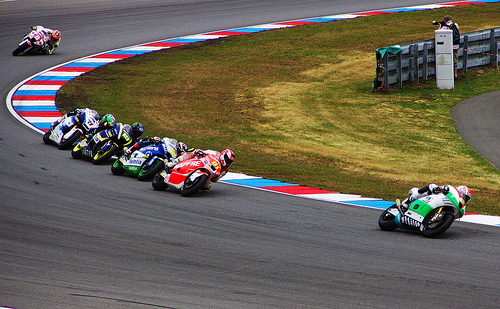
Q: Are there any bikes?
A: Yes, there is a bike.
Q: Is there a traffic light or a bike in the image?
A: Yes, there is a bike.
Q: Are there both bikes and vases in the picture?
A: No, there is a bike but no vases.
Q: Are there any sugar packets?
A: No, there are no sugar packets.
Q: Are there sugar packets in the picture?
A: No, there are no sugar packets.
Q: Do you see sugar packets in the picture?
A: No, there are no sugar packets.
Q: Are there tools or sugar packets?
A: No, there are no sugar packets or tools.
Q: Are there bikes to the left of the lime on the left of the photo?
A: Yes, there is a bike to the left of the lime.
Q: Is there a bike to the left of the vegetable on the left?
A: Yes, there is a bike to the left of the lime.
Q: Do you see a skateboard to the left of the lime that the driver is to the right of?
A: No, there is a bike to the left of the lime.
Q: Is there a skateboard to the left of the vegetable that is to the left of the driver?
A: No, there is a bike to the left of the lime.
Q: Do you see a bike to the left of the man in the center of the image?
A: Yes, there is a bike to the left of the man.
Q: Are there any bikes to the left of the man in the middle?
A: Yes, there is a bike to the left of the man.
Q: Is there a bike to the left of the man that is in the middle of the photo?
A: Yes, there is a bike to the left of the man.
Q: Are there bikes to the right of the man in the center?
A: No, the bike is to the left of the man.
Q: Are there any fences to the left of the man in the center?
A: No, there is a bike to the left of the man.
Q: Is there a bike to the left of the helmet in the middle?
A: Yes, there is a bike to the left of the helmet.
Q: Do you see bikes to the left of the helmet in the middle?
A: Yes, there is a bike to the left of the helmet.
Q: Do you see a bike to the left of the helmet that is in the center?
A: Yes, there is a bike to the left of the helmet.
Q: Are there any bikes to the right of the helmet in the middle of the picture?
A: No, the bike is to the left of the helmet.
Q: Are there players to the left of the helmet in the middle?
A: No, there is a bike to the left of the helmet.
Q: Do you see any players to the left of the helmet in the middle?
A: No, there is a bike to the left of the helmet.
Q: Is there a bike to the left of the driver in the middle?
A: Yes, there is a bike to the left of the driver.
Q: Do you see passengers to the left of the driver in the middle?
A: No, there is a bike to the left of the driver.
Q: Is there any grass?
A: Yes, there is grass.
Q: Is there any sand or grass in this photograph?
A: Yes, there is grass.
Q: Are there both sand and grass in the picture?
A: No, there is grass but no sand.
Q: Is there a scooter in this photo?
A: No, there are no scooters.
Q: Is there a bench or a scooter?
A: No, there are no scooters or benches.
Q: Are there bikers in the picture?
A: Yes, there is a biker.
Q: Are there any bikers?
A: Yes, there is a biker.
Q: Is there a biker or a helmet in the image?
A: Yes, there is a biker.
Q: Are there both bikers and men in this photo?
A: Yes, there are both a biker and men.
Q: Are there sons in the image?
A: No, there are no sons.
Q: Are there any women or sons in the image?
A: No, there are no sons or women.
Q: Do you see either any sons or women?
A: No, there are no sons or women.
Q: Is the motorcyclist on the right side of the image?
A: Yes, the motorcyclist is on the right of the image.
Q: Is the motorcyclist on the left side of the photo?
A: No, the motorcyclist is on the right of the image.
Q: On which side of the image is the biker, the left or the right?
A: The biker is on the right of the image.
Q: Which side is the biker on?
A: The biker is on the right of the image.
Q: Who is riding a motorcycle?
A: The biker is riding a motorcycle.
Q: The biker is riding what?
A: The biker is riding a motorcycle.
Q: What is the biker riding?
A: The biker is riding a motorcycle.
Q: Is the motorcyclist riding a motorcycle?
A: Yes, the motorcyclist is riding a motorcycle.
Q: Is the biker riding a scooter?
A: No, the biker is riding a motorcycle.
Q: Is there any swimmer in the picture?
A: No, there are no swimmers.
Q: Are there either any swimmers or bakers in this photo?
A: No, there are no swimmers or bakers.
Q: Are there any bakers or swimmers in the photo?
A: No, there are no swimmers or bakers.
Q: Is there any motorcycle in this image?
A: Yes, there is a motorcycle.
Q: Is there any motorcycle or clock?
A: Yes, there is a motorcycle.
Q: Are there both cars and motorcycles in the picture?
A: No, there is a motorcycle but no cars.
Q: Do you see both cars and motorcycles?
A: No, there is a motorcycle but no cars.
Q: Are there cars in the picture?
A: No, there are no cars.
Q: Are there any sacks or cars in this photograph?
A: No, there are no cars or sacks.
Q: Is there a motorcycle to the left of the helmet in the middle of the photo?
A: Yes, there is a motorcycle to the left of the helmet.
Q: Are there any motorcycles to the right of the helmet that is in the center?
A: No, the motorcycle is to the left of the helmet.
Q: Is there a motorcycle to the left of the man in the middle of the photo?
A: Yes, there is a motorcycle to the left of the man.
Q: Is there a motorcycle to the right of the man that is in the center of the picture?
A: No, the motorcycle is to the left of the man.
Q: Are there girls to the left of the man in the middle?
A: No, there is a motorcycle to the left of the man.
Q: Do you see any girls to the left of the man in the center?
A: No, there is a motorcycle to the left of the man.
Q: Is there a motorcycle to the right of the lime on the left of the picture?
A: Yes, there is a motorcycle to the right of the lime.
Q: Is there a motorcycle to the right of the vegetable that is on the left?
A: Yes, there is a motorcycle to the right of the lime.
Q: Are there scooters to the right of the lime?
A: No, there is a motorcycle to the right of the lime.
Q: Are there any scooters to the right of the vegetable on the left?
A: No, there is a motorcycle to the right of the lime.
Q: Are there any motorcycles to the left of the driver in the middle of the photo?
A: Yes, there is a motorcycle to the left of the driver.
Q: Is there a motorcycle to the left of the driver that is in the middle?
A: Yes, there is a motorcycle to the left of the driver.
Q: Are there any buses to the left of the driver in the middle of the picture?
A: No, there is a motorcycle to the left of the driver.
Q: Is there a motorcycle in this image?
A: Yes, there is a motorcycle.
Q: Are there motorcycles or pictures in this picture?
A: Yes, there is a motorcycle.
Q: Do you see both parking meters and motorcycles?
A: No, there is a motorcycle but no parking meters.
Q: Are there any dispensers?
A: No, there are no dispensers.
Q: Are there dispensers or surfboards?
A: No, there are no dispensers or surfboards.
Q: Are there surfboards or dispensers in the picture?
A: No, there are no dispensers or surfboards.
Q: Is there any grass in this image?
A: Yes, there is grass.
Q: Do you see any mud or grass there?
A: Yes, there is grass.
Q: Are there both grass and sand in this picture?
A: No, there is grass but no sand.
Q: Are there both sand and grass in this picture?
A: No, there is grass but no sand.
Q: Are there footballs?
A: No, there are no footballs.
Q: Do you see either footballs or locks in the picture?
A: No, there are no footballs or locks.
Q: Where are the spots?
A: The spots are on the road.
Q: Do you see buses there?
A: No, there are no buses.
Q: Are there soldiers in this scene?
A: No, there are no soldiers.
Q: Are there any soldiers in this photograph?
A: No, there are no soldiers.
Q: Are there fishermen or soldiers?
A: No, there are no soldiers or fishermen.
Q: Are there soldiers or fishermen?
A: No, there are no soldiers or fishermen.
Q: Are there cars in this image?
A: No, there are no cars.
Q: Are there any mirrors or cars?
A: No, there are no cars or mirrors.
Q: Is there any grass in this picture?
A: Yes, there is grass.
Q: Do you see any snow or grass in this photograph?
A: Yes, there is grass.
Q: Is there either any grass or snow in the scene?
A: Yes, there is grass.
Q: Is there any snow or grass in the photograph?
A: Yes, there is grass.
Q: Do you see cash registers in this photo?
A: No, there are no cash registers.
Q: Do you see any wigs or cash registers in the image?
A: No, there are no cash registers or wigs.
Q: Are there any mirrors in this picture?
A: No, there are no mirrors.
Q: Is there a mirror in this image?
A: No, there are no mirrors.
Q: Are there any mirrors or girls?
A: No, there are no mirrors or girls.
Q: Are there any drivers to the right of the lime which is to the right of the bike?
A: Yes, there is a driver to the right of the lime.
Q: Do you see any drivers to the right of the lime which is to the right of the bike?
A: Yes, there is a driver to the right of the lime.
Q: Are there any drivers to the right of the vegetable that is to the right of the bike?
A: Yes, there is a driver to the right of the lime.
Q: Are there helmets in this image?
A: Yes, there is a helmet.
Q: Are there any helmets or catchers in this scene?
A: Yes, there is a helmet.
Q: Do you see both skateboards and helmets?
A: No, there is a helmet but no skateboards.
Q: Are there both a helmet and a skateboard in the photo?
A: No, there is a helmet but no skateboards.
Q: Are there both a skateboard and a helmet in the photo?
A: No, there is a helmet but no skateboards.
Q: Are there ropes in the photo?
A: No, there are no ropes.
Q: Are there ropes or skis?
A: No, there are no ropes or skis.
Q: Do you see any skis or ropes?
A: No, there are no ropes or skis.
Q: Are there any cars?
A: No, there are no cars.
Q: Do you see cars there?
A: No, there are no cars.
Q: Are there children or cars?
A: No, there are no cars or children.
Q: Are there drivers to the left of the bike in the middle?
A: Yes, there is a driver to the left of the bike.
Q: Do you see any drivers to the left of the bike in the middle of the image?
A: Yes, there is a driver to the left of the bike.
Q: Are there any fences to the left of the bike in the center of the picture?
A: No, there is a driver to the left of the bike.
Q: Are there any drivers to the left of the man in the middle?
A: Yes, there is a driver to the left of the man.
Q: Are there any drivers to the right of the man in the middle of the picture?
A: No, the driver is to the left of the man.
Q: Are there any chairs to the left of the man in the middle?
A: No, there is a driver to the left of the man.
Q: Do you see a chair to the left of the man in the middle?
A: No, there is a driver to the left of the man.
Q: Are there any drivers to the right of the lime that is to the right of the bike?
A: Yes, there is a driver to the right of the lime.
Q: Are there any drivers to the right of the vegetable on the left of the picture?
A: Yes, there is a driver to the right of the lime.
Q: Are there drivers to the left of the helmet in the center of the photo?
A: Yes, there is a driver to the left of the helmet.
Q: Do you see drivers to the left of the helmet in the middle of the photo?
A: Yes, there is a driver to the left of the helmet.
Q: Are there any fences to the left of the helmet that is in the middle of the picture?
A: No, there is a driver to the left of the helmet.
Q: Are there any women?
A: No, there are no women.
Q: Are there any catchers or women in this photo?
A: No, there are no women or catchers.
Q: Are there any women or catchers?
A: No, there are no women or catchers.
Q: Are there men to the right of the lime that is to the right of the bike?
A: Yes, there is a man to the right of the lime.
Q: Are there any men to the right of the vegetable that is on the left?
A: Yes, there is a man to the right of the lime.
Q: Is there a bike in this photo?
A: Yes, there is a bike.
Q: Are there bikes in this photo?
A: Yes, there is a bike.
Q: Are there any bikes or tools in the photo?
A: Yes, there is a bike.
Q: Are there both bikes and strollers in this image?
A: No, there is a bike but no strollers.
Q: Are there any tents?
A: No, there are no tents.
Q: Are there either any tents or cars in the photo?
A: No, there are no tents or cars.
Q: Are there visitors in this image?
A: No, there are no visitors.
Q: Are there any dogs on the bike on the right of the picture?
A: No, there is a man on the bike.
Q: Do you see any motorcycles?
A: Yes, there is a motorcycle.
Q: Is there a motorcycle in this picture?
A: Yes, there is a motorcycle.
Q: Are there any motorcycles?
A: Yes, there is a motorcycle.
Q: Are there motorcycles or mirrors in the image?
A: Yes, there is a motorcycle.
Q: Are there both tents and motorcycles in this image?
A: No, there is a motorcycle but no tents.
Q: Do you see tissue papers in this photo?
A: No, there are no tissue papers.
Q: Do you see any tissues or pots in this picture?
A: No, there are no tissues or pots.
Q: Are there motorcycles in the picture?
A: Yes, there is a motorcycle.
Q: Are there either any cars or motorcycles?
A: Yes, there is a motorcycle.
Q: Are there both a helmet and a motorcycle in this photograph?
A: Yes, there are both a motorcycle and a helmet.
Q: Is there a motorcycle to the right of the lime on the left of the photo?
A: Yes, there is a motorcycle to the right of the lime.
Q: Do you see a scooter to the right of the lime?
A: No, there is a motorcycle to the right of the lime.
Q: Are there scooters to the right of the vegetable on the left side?
A: No, there is a motorcycle to the right of the lime.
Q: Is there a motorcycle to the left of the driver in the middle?
A: Yes, there is a motorcycle to the left of the driver.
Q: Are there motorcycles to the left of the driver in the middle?
A: Yes, there is a motorcycle to the left of the driver.